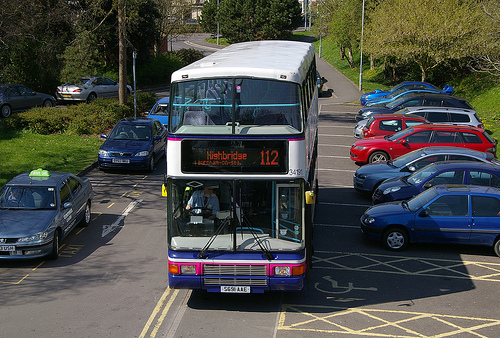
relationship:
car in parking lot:
[345, 122, 497, 167] [2, 86, 499, 336]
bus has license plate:
[163, 36, 322, 296] [220, 286, 251, 294]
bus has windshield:
[163, 36, 322, 296] [162, 176, 307, 263]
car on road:
[0, 167, 94, 260] [9, 128, 497, 336]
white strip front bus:
[165, 252, 309, 270] [143, 15, 331, 306]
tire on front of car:
[387, 231, 406, 249] [366, 187, 498, 254]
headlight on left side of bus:
[180, 264, 199, 274] [118, 21, 333, 336]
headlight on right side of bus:
[180, 264, 197, 274] [163, 68, 310, 291]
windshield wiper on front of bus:
[240, 212, 262, 249] [163, 34, 353, 314]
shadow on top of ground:
[310, 243, 460, 294] [320, 251, 496, 332]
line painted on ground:
[148, 306, 170, 335] [0, 290, 493, 336]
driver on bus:
[180, 177, 225, 217] [163, 36, 322, 296]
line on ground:
[148, 306, 170, 335] [0, 36, 496, 337]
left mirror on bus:
[301, 187, 320, 207] [163, 36, 322, 296]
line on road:
[148, 306, 170, 335] [43, 25, 494, 329]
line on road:
[153, 306, 169, 335] [43, 25, 494, 329]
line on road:
[139, 290, 154, 336] [43, 25, 494, 329]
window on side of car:
[417, 190, 468, 216] [354, 167, 499, 261]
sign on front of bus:
[175, 135, 289, 177] [163, 36, 322, 296]